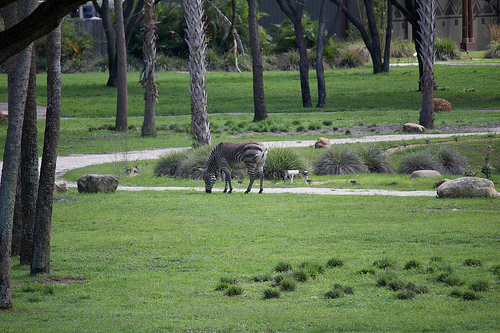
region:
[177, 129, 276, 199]
a zebra standing in a field.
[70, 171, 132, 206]
an object on the grass.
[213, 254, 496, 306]
a cluster of wild crab grass.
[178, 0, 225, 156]
a tree in a field.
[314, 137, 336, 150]
a rock near a road.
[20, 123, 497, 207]
a dirt road in a park.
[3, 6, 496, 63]
a forest of plants.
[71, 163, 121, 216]
a large rock.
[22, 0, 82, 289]
a skinny tree.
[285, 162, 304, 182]
a white sign.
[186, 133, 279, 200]
zebra grazing on the gras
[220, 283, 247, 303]
tiny puffy plant growing out of the grass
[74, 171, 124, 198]
big rectangular boulder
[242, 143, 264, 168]
black and white stripes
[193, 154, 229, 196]
head angled down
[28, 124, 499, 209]
grayish walking path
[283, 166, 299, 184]
tiny white thing sticking out of the grass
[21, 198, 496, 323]
patch of green grass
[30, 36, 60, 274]
thin, dark tree trunk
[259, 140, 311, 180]
pointy, dark green bush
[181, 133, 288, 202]
an adult giraffe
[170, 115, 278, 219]
a giraffe eating grass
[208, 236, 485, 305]
little patches of grass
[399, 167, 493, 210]
a big rock on the grass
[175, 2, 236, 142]
tall palm trees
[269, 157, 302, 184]
light that is off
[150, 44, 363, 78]
bushes on top of the grass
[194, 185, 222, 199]
the giraffes mouth is black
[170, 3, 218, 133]
the tree is spiky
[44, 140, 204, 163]
the path is made of dirt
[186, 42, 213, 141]
a trunk of a tree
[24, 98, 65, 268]
a trunk of a tree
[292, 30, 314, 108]
a trunk of a tree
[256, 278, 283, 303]
tuffs of grass in a field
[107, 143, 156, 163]
a gravel road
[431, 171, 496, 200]
a big bolder in a field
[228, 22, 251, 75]
a branch of a tree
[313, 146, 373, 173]
flowers in a yard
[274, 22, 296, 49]
leaves of a tree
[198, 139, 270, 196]
a animal eating grass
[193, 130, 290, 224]
Zebra grazing on grass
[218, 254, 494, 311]
clumps of grass on field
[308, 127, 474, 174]
Huge plooms of grass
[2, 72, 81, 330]
Four tall trees growing close together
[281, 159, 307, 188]
A light lining the path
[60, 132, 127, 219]
Large boulder by the path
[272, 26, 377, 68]
Huge amount of bushes together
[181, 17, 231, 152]
Textured bark on palm tree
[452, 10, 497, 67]
Building wall behind trees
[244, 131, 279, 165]
Short zebra tail